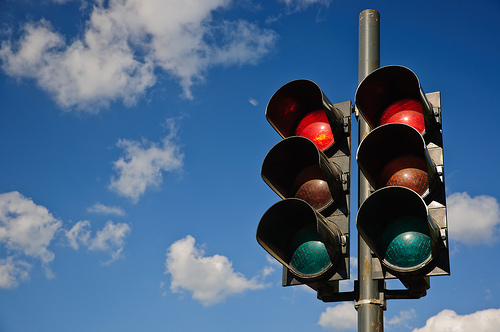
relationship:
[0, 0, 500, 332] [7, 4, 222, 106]
sky with clouds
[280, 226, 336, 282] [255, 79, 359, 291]
light on light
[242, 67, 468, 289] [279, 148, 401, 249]
stop lights have black cases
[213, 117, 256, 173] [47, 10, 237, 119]
sky with clouds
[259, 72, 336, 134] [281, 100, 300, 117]
casing casting shadow